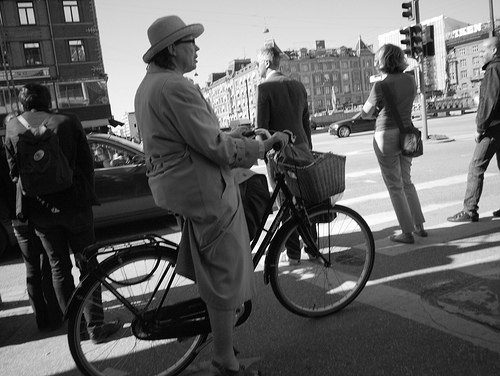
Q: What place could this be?
A: It is a street.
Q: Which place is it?
A: It is a street.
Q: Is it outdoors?
A: Yes, it is outdoors.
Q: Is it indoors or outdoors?
A: It is outdoors.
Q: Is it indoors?
A: No, it is outdoors.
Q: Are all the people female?
A: No, they are both male and female.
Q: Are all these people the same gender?
A: No, they are both male and female.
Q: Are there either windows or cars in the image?
A: Yes, there is a window.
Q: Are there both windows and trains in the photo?
A: No, there is a window but no trains.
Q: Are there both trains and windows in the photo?
A: No, there is a window but no trains.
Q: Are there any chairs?
A: No, there are no chairs.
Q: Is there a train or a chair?
A: No, there are no chairs or trains.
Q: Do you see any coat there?
A: Yes, there is a coat.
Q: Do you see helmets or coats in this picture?
A: Yes, there is a coat.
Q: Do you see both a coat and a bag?
A: Yes, there are both a coat and a bag.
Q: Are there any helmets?
A: No, there are no helmets.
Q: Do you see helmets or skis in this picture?
A: No, there are no helmets or skis.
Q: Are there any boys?
A: No, there are no boys.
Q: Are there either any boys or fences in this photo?
A: No, there are no boys or fences.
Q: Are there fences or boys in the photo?
A: No, there are no boys or fences.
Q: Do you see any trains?
A: No, there are no trains.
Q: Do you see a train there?
A: No, there are no trains.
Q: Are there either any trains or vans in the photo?
A: No, there are no trains or vans.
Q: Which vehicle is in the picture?
A: The vehicle is a car.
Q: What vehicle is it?
A: The vehicle is a car.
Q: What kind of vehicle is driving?
A: The vehicle is a car.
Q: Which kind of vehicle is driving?
A: The vehicle is a car.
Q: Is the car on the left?
A: Yes, the car is on the left of the image.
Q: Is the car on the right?
A: No, the car is on the left of the image.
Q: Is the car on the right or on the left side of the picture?
A: The car is on the left of the image.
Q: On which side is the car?
A: The car is on the left of the image.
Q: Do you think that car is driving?
A: Yes, the car is driving.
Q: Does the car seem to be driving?
A: Yes, the car is driving.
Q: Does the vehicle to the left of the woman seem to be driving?
A: Yes, the car is driving.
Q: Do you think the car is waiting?
A: No, the car is driving.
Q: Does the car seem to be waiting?
A: No, the car is driving.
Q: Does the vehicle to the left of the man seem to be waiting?
A: No, the car is driving.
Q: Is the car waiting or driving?
A: The car is driving.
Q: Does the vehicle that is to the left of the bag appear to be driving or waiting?
A: The car is driving.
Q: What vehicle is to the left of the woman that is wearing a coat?
A: The vehicle is a car.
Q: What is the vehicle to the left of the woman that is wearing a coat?
A: The vehicle is a car.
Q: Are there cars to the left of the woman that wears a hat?
A: Yes, there is a car to the left of the woman.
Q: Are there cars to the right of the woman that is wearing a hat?
A: No, the car is to the left of the woman.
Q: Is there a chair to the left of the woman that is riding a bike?
A: No, there is a car to the left of the woman.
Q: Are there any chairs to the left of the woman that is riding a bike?
A: No, there is a car to the left of the woman.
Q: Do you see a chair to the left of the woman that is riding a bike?
A: No, there is a car to the left of the woman.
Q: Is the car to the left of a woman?
A: Yes, the car is to the left of a woman.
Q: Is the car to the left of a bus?
A: No, the car is to the left of a woman.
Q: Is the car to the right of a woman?
A: No, the car is to the left of a woman.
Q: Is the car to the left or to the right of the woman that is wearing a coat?
A: The car is to the left of the woman.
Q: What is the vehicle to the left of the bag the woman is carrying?
A: The vehicle is a car.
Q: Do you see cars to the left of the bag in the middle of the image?
A: Yes, there is a car to the left of the bag.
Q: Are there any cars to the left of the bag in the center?
A: Yes, there is a car to the left of the bag.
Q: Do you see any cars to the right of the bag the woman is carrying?
A: No, the car is to the left of the bag.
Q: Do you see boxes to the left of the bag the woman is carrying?
A: No, there is a car to the left of the bag.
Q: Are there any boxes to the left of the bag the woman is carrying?
A: No, there is a car to the left of the bag.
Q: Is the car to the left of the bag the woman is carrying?
A: Yes, the car is to the left of the bag.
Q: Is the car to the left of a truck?
A: No, the car is to the left of the bag.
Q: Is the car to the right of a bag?
A: No, the car is to the left of a bag.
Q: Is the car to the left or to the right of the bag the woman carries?
A: The car is to the left of the bag.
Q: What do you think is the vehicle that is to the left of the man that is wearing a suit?
A: The vehicle is a car.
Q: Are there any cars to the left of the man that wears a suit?
A: Yes, there is a car to the left of the man.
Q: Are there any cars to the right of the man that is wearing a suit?
A: No, the car is to the left of the man.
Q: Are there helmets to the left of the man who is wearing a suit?
A: No, there is a car to the left of the man.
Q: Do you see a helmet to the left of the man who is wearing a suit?
A: No, there is a car to the left of the man.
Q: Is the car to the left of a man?
A: Yes, the car is to the left of a man.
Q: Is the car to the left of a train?
A: No, the car is to the left of a man.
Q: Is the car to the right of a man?
A: No, the car is to the left of a man.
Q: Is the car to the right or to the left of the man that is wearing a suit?
A: The car is to the left of the man.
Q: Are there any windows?
A: Yes, there is a window.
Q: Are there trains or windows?
A: Yes, there is a window.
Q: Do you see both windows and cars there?
A: Yes, there are both a window and a car.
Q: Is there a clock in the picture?
A: No, there are no clocks.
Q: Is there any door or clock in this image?
A: No, there are no clocks or doors.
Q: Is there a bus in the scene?
A: No, there are no buses.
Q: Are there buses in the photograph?
A: No, there are no buses.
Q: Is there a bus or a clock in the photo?
A: No, there are no buses or clocks.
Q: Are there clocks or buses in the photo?
A: No, there are no buses or clocks.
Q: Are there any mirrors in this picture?
A: No, there are no mirrors.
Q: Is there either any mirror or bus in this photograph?
A: No, there are no mirrors or buses.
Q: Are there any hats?
A: Yes, there is a hat.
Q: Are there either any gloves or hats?
A: Yes, there is a hat.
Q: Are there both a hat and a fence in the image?
A: No, there is a hat but no fences.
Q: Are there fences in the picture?
A: No, there are no fences.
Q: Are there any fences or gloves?
A: No, there are no fences or gloves.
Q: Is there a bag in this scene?
A: Yes, there is a bag.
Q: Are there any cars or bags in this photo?
A: Yes, there is a bag.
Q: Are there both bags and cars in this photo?
A: Yes, there are both a bag and a car.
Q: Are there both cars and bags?
A: Yes, there are both a bag and a car.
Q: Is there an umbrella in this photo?
A: No, there are no umbrellas.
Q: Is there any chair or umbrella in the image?
A: No, there are no umbrellas or chairs.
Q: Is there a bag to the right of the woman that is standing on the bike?
A: Yes, there is a bag to the right of the woman.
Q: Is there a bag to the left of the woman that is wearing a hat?
A: No, the bag is to the right of the woman.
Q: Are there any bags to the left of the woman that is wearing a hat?
A: No, the bag is to the right of the woman.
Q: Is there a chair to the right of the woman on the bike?
A: No, there is a bag to the right of the woman.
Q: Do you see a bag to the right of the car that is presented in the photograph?
A: Yes, there is a bag to the right of the car.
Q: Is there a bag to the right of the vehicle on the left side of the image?
A: Yes, there is a bag to the right of the car.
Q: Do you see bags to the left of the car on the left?
A: No, the bag is to the right of the car.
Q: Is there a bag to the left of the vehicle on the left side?
A: No, the bag is to the right of the car.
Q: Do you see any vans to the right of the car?
A: No, there is a bag to the right of the car.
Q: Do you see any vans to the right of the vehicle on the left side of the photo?
A: No, there is a bag to the right of the car.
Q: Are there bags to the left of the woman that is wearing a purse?
A: Yes, there is a bag to the left of the woman.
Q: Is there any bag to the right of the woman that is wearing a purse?
A: No, the bag is to the left of the woman.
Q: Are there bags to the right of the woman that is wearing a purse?
A: No, the bag is to the left of the woman.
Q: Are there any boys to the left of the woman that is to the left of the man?
A: No, there is a bag to the left of the woman.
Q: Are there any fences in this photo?
A: No, there are no fences.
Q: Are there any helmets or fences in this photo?
A: No, there are no fences or helmets.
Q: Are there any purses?
A: Yes, there is a purse.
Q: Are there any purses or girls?
A: Yes, there is a purse.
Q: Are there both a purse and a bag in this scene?
A: Yes, there are both a purse and a bag.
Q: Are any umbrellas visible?
A: No, there are no umbrellas.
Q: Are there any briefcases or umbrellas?
A: No, there are no umbrellas or briefcases.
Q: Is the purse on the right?
A: Yes, the purse is on the right of the image.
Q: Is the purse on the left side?
A: No, the purse is on the right of the image.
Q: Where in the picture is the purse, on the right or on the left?
A: The purse is on the right of the image.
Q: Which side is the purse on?
A: The purse is on the right of the image.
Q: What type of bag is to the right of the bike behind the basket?
A: The bag is a purse.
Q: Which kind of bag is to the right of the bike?
A: The bag is a purse.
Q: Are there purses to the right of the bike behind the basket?
A: Yes, there is a purse to the right of the bike.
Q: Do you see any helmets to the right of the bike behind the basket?
A: No, there is a purse to the right of the bike.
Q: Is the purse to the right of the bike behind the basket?
A: Yes, the purse is to the right of the bike.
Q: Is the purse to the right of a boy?
A: No, the purse is to the right of the bike.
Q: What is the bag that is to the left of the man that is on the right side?
A: The bag is a purse.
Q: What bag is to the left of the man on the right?
A: The bag is a purse.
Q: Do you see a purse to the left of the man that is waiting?
A: Yes, there is a purse to the left of the man.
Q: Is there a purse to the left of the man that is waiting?
A: Yes, there is a purse to the left of the man.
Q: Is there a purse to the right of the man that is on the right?
A: No, the purse is to the left of the man.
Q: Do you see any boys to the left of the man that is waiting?
A: No, there is a purse to the left of the man.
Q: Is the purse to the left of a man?
A: Yes, the purse is to the left of a man.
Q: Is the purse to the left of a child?
A: No, the purse is to the left of a man.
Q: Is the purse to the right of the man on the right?
A: No, the purse is to the left of the man.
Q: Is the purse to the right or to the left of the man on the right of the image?
A: The purse is to the left of the man.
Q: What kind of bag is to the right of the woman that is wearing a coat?
A: The bag is a purse.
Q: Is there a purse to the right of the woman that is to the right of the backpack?
A: Yes, there is a purse to the right of the woman.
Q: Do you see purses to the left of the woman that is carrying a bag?
A: No, the purse is to the right of the woman.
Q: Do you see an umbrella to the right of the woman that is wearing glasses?
A: No, there is a purse to the right of the woman.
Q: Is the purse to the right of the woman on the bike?
A: Yes, the purse is to the right of the woman.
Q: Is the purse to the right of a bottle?
A: No, the purse is to the right of the woman.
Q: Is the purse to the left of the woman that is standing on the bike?
A: No, the purse is to the right of the woman.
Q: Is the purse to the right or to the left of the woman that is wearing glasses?
A: The purse is to the right of the woman.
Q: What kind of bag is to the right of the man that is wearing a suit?
A: The bag is a purse.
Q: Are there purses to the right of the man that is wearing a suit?
A: Yes, there is a purse to the right of the man.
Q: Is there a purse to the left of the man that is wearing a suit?
A: No, the purse is to the right of the man.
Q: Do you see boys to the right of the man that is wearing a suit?
A: No, there is a purse to the right of the man.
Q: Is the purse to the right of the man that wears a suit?
A: Yes, the purse is to the right of the man.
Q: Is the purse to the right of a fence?
A: No, the purse is to the right of the man.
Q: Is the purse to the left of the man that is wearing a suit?
A: No, the purse is to the right of the man.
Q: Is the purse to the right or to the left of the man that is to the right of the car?
A: The purse is to the right of the man.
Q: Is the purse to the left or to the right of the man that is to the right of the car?
A: The purse is to the right of the man.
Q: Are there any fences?
A: No, there are no fences.